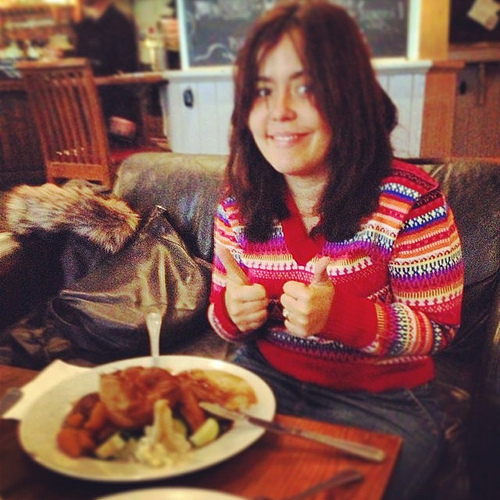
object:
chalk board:
[176, 0, 420, 68]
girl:
[208, 4, 465, 497]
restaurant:
[1, 1, 497, 498]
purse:
[52, 199, 210, 357]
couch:
[0, 157, 498, 426]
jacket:
[5, 181, 143, 374]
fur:
[0, 184, 141, 262]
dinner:
[14, 353, 279, 481]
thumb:
[211, 243, 247, 279]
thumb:
[312, 256, 332, 282]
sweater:
[205, 161, 466, 393]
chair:
[20, 56, 127, 186]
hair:
[220, 1, 402, 247]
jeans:
[228, 342, 448, 499]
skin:
[301, 110, 320, 127]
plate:
[19, 352, 280, 483]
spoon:
[144, 309, 164, 368]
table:
[3, 361, 403, 498]